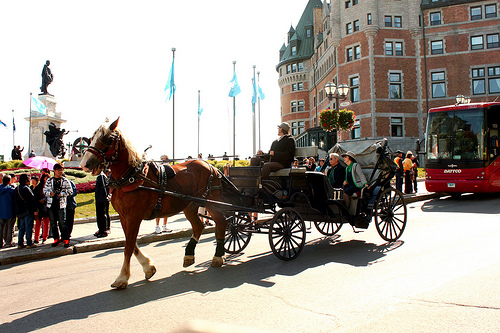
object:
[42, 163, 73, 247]
man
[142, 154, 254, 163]
curb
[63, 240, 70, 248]
shoes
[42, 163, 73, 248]
people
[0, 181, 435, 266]
sidewalk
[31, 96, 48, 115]
flags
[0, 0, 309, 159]
sky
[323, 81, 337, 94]
lamps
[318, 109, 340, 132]
lamps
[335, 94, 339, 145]
poles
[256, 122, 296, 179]
people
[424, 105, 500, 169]
front window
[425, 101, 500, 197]
bus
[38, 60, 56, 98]
statue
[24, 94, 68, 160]
pedestal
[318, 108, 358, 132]
flowers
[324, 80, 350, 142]
street lamp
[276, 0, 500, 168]
building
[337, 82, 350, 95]
light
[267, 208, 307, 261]
wheel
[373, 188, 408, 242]
wheels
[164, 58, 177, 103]
flag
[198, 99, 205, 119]
flag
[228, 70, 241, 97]
flag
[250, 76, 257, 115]
flag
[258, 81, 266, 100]
flag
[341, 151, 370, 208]
people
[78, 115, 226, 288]
horse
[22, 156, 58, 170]
umbrella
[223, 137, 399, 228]
carriage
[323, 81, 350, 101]
lamp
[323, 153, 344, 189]
passenger